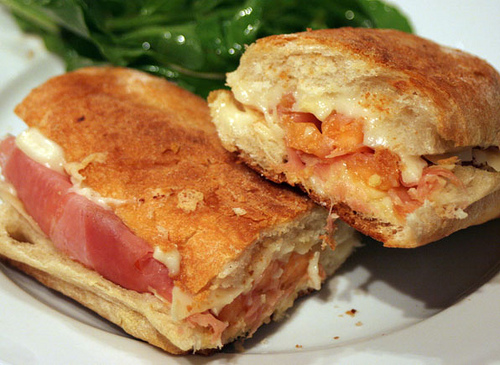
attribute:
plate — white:
[2, 1, 498, 361]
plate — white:
[338, 280, 497, 363]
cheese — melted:
[284, 86, 380, 136]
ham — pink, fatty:
[3, 144, 174, 299]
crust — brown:
[16, 65, 311, 287]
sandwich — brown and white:
[224, 34, 483, 244]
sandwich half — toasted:
[2, 64, 358, 364]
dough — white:
[237, 40, 381, 130]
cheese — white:
[344, 101, 425, 182]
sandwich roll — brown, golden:
[5, 62, 354, 349]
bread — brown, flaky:
[12, 63, 336, 294]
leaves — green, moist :
[0, 0, 415, 97]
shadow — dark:
[345, 220, 499, 317]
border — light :
[345, 268, 432, 324]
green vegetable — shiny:
[2, 0, 413, 99]